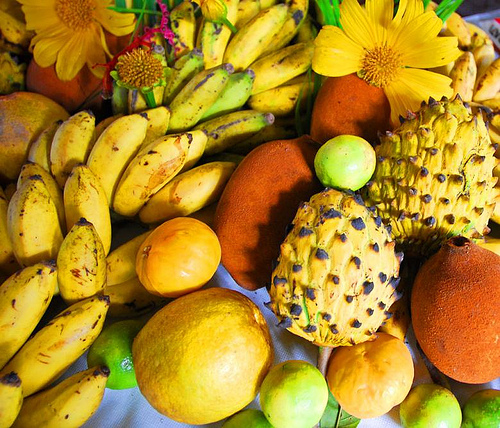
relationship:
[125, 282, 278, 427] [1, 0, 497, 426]
orange amongst fruits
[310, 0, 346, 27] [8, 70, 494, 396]
green leaves behind fruit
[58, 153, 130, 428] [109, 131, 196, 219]
bunch of banana